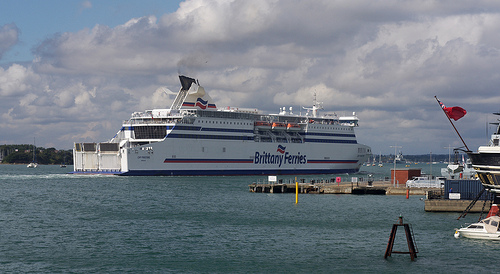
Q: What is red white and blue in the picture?
A: Boat.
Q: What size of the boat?
A: Cruise size.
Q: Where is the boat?
A: In the water.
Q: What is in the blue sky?
A: Clouds.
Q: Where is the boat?
A: In the water.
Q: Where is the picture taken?
A: Harbor.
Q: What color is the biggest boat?
A: White.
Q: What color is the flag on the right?
A: Red.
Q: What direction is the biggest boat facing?
A: Right.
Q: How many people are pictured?
A: None.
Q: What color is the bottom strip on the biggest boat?
A: Red.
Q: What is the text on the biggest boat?
A: Brittany Ferries.